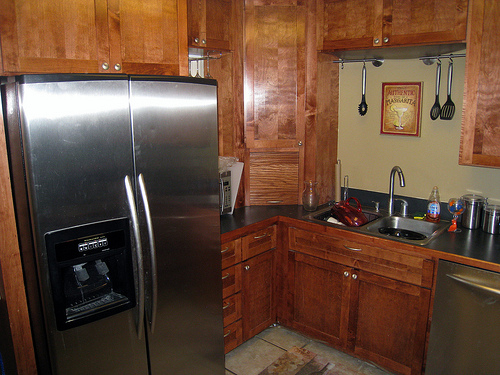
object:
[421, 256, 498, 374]
dishwasher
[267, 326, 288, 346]
ground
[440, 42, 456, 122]
utensils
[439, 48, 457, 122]
utensils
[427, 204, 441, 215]
sink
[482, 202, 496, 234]
canister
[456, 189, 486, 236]
canister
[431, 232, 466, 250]
counter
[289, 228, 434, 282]
drawer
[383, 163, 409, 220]
sink fixtures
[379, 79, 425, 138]
red-bordered picture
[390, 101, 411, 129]
trophy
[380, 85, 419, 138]
sign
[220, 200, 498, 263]
counter top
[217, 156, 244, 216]
microwave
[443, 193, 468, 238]
glass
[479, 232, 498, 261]
counter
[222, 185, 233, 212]
panel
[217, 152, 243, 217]
microwave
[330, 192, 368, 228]
pitcher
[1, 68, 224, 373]
appliance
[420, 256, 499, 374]
appliance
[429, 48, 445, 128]
kitchen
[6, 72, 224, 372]
refrigerator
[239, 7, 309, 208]
cabinet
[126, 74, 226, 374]
door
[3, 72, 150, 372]
door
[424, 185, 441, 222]
bottle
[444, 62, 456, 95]
handle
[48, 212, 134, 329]
dispenser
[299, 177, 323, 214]
vase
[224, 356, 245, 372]
tiles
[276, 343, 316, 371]
rug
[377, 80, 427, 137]
picture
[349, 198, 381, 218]
border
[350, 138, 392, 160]
wall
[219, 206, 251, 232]
counter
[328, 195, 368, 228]
dishes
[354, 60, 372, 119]
kitchen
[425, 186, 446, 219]
label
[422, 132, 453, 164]
wall